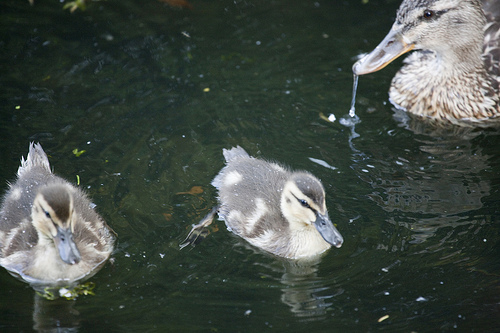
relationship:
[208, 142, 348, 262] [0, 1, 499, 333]
duck in lake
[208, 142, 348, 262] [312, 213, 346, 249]
duck has bill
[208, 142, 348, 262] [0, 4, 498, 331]
duck in water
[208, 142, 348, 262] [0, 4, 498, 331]
duck on water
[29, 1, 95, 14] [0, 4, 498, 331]
leaves in water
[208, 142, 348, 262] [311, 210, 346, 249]
duck has beak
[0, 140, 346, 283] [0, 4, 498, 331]
ducks are in water